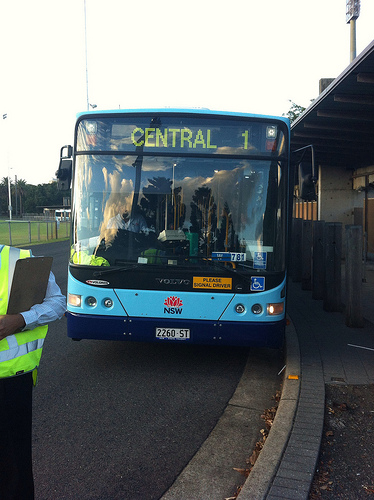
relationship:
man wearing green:
[2, 235, 40, 496] [0, 245, 49, 388]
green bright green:
[0, 245, 49, 388] [0, 246, 53, 376]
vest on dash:
[74, 250, 113, 267] [72, 250, 276, 280]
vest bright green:
[74, 250, 113, 267] [68, 244, 115, 267]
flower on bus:
[160, 293, 187, 310] [60, 108, 313, 347]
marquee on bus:
[131, 127, 248, 149] [60, 108, 313, 347]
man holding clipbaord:
[2, 235, 40, 496] [2, 256, 55, 317]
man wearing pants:
[2, 235, 40, 496] [0, 372, 38, 499]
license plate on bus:
[157, 328, 192, 342] [60, 108, 313, 347]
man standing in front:
[2, 235, 40, 496] [53, 110, 317, 347]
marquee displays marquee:
[99, 120, 260, 151] [131, 127, 248, 149]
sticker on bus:
[189, 274, 233, 295] [53, 110, 317, 347]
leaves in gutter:
[227, 349, 287, 487] [222, 345, 294, 499]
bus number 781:
[53, 110, 317, 347] [229, 252, 247, 264]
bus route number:
[53, 110, 317, 347] [235, 124, 254, 157]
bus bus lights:
[60, 108, 313, 347] [70, 291, 284, 314]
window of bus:
[80, 157, 283, 263] [53, 110, 317, 347]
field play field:
[0, 220, 70, 247] [2, 219, 74, 250]